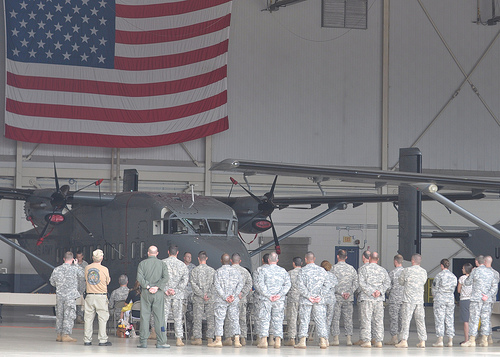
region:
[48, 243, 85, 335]
serviceman standing in a line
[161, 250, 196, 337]
serviceman standing in a line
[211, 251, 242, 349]
serviceman standing in a line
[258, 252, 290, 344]
serviceman standing in a line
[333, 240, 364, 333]
serviceman standing in a line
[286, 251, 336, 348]
serviceman standing in a line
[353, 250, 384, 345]
serviceman standing in a line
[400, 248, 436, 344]
serviceman standing in a line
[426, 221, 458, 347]
serviceman standing in a line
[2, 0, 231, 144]
American flag hanging over plane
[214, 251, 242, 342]
soldier standing in front of plane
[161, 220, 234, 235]
window on the plane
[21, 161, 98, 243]
propellar on the plane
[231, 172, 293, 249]
propellar on the plane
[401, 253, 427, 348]
soldier in front of plane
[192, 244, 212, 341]
soldier in front of plane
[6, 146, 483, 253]
airplane in the hanger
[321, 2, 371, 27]
air vent on wall in plane hanger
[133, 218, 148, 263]
door on the airplane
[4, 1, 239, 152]
american flag on the building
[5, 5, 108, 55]
stars on the flag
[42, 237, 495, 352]
group of military men and women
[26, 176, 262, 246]
plane in front of the men and women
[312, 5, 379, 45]
window on the building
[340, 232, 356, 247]
exit sign above the door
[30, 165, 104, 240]
propeller on the plane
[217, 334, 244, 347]
boots on the men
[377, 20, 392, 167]
white pole going up the side of the building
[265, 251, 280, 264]
man with gray hair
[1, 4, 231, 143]
large American flag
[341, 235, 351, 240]
small yellow sign above the door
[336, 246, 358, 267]
blue closed door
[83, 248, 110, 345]
person in a peach shirt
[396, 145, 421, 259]
tall grey metal pillar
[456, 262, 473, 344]
woman in white shirt and gray skirt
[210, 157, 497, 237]
wing of a different plane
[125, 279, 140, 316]
woman wearing black sitting on a folding chair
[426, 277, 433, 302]
yellow metal object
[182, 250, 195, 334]
man looking at everyone else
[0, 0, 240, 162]
a giant american flag.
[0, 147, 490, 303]
a plane parked under a flag.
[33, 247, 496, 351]
a group of soldiers.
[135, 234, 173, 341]
a soldier in uniform.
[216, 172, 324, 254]
a propeller on a plane.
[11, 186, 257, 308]
The body of a green plane.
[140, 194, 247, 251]
a window on an airplane.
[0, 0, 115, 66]
stars on an american flag.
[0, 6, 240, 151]
A giant flag.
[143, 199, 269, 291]
the front of an airplane.